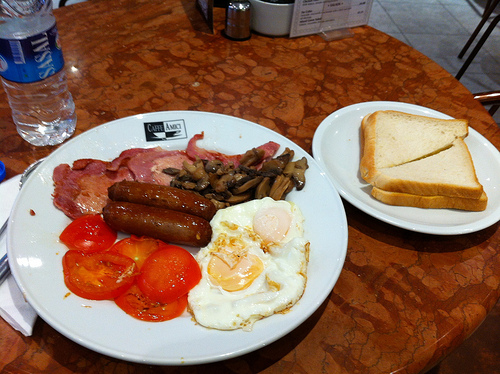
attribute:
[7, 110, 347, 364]
plate — white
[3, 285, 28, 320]
napkin — white 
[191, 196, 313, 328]
egg — cooked 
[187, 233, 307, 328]
egg — cooked 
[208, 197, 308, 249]
egg — cooked 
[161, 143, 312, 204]
mushrooms — cooked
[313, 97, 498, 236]
plate — white